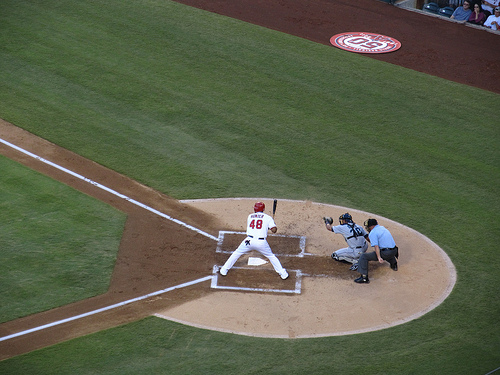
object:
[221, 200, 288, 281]
player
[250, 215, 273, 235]
red and white